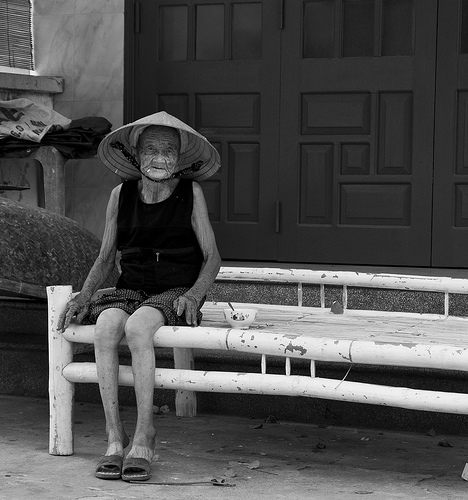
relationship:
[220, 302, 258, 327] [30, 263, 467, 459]
bowl on bench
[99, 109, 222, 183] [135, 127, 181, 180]
hat on head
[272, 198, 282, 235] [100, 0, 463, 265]
hinge on door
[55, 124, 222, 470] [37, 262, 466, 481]
person on bench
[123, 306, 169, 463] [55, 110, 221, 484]
leg of person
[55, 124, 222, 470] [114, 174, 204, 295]
person wearing shirt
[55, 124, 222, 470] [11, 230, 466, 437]
person sitting on bench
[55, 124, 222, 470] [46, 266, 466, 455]
person sitting on bench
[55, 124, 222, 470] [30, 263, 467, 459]
person sitting on bench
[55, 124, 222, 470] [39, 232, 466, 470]
person sitting on bench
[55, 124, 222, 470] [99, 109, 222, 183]
person wearing hat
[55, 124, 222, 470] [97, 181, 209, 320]
person wearing skirt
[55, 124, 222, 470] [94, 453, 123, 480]
person wearing shoes